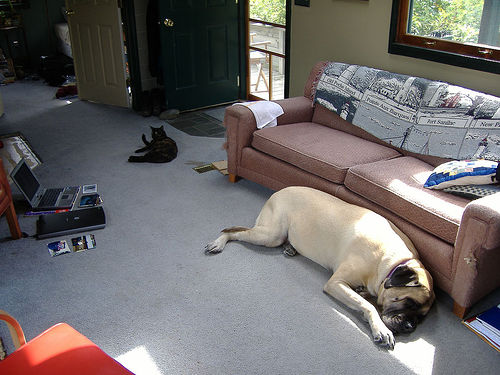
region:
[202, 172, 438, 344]
a dog sleeping on a carpet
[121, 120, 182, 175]
a black cat on a gray carpet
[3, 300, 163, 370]
edge of a red chair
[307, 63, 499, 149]
a throw spread on a couch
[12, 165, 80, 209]
a laptop on a carpet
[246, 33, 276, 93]
a wooden chair on a balcony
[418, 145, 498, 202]
a white and blue cushion on a couch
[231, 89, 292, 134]
a white towel on a couch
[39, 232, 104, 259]
two photos on a gray carpet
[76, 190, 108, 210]
a blue CD case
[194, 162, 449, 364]
huge tan dog is sleeping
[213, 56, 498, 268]
pink tan couch with blanket on the back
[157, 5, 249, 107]
door in front is open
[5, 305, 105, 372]
red chair with wood arms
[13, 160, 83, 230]
laptop on the carpet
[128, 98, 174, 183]
black cat sleeping on the carpet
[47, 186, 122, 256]
CD's in front of laptop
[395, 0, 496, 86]
window behing the couch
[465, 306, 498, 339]
books on the floor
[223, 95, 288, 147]
white towel on the edge of the couch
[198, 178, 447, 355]
dog on the floor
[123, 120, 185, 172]
black cat on the floor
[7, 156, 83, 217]
laptop computer on the floor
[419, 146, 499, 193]
pillow on a couch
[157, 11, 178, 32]
knob on a door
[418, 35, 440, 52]
handle on a window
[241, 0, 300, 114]
screen door in a room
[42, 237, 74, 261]
compact disk case on a floor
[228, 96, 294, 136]
towel on the arm of a couch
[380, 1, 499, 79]
window in a room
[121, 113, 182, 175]
Black cat on carpet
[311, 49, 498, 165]
Blanket hanging on back of sofa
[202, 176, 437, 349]
Large dog laying on floor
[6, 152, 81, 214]
Gray laptop on floor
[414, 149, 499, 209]
Blue and white pillow on sofa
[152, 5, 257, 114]
Front door painted green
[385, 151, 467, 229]
Sun reflected on sofa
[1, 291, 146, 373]
Chair with orange cushion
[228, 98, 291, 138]
White towel hanging across sofa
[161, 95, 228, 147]
Patch of tile near door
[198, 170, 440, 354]
the dog is laying down.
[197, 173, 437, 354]
the dog is blonde.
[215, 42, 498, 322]
the couch is brown.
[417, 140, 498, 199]
a pillow on the couch.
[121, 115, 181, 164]
the cat is laying down.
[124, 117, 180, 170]
the cat is brown.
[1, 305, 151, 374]
the chair is orange.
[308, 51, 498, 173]
blanket on the couch.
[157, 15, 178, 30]
the doorknob is golden.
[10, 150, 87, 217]
laptop on the ground.